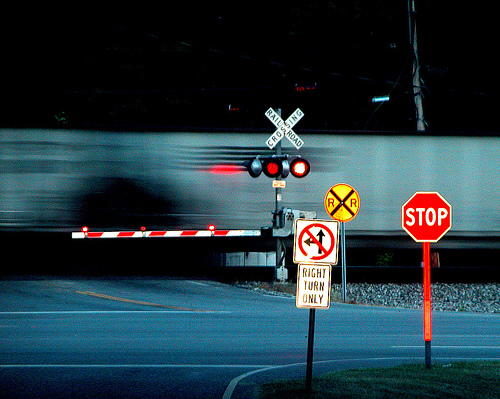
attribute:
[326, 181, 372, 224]
sign — yellow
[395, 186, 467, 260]
sign — red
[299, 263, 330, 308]
sign — red, white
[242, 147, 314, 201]
lights — red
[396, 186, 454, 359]
stop sign — red, white, metal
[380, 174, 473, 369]
sign — yellow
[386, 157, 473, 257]
sign — yellow, black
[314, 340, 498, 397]
area — grassy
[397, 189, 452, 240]
sign — red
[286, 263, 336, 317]
right turn — white, black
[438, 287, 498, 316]
gray rocks — grey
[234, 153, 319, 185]
light — on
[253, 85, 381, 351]
signs — metal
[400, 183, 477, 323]
sign pole — red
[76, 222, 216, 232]
lights — red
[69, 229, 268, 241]
guard rail — red, white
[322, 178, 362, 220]
sign — black, yellow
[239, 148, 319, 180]
lights — red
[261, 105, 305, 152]
sign — white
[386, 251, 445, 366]
pole — red